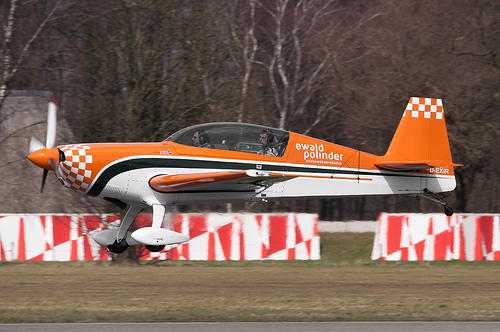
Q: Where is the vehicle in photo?
A: Slightly off ground.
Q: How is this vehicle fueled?
A: Gasoline.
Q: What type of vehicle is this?
A: Airplane.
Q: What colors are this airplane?
A: Orange and white.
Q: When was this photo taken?
A: Daytime.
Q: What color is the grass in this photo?
A: Brownish-green.